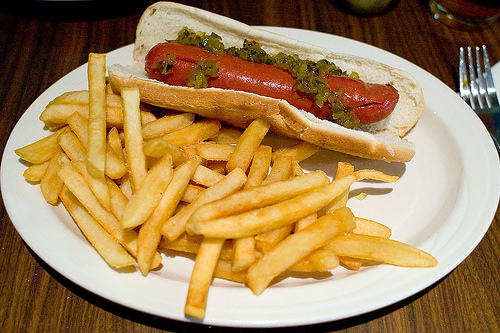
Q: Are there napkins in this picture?
A: No, there are no napkins.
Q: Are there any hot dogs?
A: Yes, there is a hot dog.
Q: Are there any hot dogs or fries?
A: Yes, there is a hot dog.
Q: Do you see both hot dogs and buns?
A: Yes, there are both a hot dog and a bun.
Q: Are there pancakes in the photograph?
A: No, there are no pancakes.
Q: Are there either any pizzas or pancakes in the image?
A: No, there are no pancakes or pizzas.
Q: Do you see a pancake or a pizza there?
A: No, there are no pancakes or pizzas.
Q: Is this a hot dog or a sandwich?
A: This is a hot dog.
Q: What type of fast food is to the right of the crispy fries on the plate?
A: The food is a hot dog.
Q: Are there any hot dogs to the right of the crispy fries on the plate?
A: Yes, there is a hot dog to the right of the fries.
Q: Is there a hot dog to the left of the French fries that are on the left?
A: No, the hot dog is to the right of the French fries.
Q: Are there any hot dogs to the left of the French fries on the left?
A: No, the hot dog is to the right of the French fries.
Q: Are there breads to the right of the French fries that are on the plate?
A: No, there is a hot dog to the right of the fries.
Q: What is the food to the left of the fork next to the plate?
A: The food is a hot dog.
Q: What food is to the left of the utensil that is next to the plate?
A: The food is a hot dog.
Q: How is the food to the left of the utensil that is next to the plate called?
A: The food is a hot dog.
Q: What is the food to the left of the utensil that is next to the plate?
A: The food is a hot dog.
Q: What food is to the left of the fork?
A: The food is a hot dog.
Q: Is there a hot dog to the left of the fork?
A: Yes, there is a hot dog to the left of the fork.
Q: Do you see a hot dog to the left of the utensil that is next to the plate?
A: Yes, there is a hot dog to the left of the fork.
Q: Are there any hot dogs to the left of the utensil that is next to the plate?
A: Yes, there is a hot dog to the left of the fork.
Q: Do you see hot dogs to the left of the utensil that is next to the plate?
A: Yes, there is a hot dog to the left of the fork.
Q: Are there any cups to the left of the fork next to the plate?
A: No, there is a hot dog to the left of the fork.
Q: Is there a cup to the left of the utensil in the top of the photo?
A: No, there is a hot dog to the left of the fork.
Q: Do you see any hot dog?
A: Yes, there is a hot dog.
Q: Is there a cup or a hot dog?
A: Yes, there is a hot dog.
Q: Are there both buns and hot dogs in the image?
A: Yes, there are both a hot dog and a bun.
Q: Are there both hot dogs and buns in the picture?
A: Yes, there are both a hot dog and a bun.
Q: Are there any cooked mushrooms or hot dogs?
A: Yes, there is a cooked hot dog.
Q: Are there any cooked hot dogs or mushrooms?
A: Yes, there is a cooked hot dog.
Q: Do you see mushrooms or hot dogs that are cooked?
A: Yes, the hot dog is cooked.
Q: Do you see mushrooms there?
A: No, there are no mushrooms.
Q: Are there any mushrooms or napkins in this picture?
A: No, there are no mushrooms or napkins.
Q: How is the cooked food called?
A: The food is a hot dog.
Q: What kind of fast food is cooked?
A: The fast food is a hot dog.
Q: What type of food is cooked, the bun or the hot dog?
A: The hot dog is cooked.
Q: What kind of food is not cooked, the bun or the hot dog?
A: The bun is not cooked.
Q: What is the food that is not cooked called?
A: The food is a bun.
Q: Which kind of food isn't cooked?
A: The food is a bun.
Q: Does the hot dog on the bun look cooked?
A: Yes, the hot dog is cooked.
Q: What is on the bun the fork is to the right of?
A: The hot dog is on the bun.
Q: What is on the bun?
A: The hot dog is on the bun.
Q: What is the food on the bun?
A: The food is a hot dog.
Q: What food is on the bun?
A: The food is a hot dog.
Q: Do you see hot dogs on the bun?
A: Yes, there is a hot dog on the bun.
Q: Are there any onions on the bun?
A: No, there is a hot dog on the bun.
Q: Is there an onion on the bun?
A: No, there is a hot dog on the bun.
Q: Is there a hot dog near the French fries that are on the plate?
A: Yes, there is a hot dog near the French fries.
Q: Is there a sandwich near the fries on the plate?
A: No, there is a hot dog near the French fries.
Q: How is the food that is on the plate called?
A: The food is a hot dog.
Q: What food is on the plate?
A: The food is a hot dog.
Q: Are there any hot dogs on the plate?
A: Yes, there is a hot dog on the plate.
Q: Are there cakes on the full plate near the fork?
A: No, there is a hot dog on the plate.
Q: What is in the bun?
A: The hot dog is in the bun.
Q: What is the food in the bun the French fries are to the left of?
A: The food is a hot dog.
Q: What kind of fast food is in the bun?
A: The food is a hot dog.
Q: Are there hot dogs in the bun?
A: Yes, there is a hot dog in the bun.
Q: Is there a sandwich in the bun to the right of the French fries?
A: No, there is a hot dog in the bun.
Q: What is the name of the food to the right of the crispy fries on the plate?
A: The food is a hot dog.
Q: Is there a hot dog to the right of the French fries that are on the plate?
A: Yes, there is a hot dog to the right of the French fries.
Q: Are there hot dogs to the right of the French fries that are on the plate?
A: Yes, there is a hot dog to the right of the French fries.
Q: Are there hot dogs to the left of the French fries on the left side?
A: No, the hot dog is to the right of the fries.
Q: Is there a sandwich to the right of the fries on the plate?
A: No, there is a hot dog to the right of the fries.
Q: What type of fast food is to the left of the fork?
A: The food is a hot dog.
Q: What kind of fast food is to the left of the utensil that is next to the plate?
A: The food is a hot dog.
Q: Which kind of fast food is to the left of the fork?
A: The food is a hot dog.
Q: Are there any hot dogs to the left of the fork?
A: Yes, there is a hot dog to the left of the fork.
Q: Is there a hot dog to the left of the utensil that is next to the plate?
A: Yes, there is a hot dog to the left of the fork.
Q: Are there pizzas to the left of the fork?
A: No, there is a hot dog to the left of the fork.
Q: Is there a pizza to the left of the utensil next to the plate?
A: No, there is a hot dog to the left of the fork.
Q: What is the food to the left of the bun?
A: The food is fries.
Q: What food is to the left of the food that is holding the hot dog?
A: The food is fries.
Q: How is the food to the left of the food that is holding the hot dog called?
A: The food is fries.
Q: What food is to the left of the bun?
A: The food is fries.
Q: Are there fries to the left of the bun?
A: Yes, there are fries to the left of the bun.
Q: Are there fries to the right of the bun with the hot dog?
A: No, the fries are to the left of the bun.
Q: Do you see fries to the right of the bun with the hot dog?
A: No, the fries are to the left of the bun.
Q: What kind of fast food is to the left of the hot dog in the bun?
A: The food is fries.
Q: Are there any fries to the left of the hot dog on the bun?
A: Yes, there are fries to the left of the hot dog.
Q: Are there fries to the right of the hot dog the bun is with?
A: No, the fries are to the left of the hot dog.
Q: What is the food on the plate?
A: The food is fries.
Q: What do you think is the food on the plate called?
A: The food is fries.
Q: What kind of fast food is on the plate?
A: The food is fries.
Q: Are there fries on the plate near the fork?
A: Yes, there are fries on the plate.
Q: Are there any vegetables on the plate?
A: No, there are fries on the plate.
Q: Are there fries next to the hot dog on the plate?
A: Yes, there are fries next to the hot dog.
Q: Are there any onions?
A: No, there are no onions.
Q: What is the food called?
A: The food is a bun.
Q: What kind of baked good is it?
A: The food is a bun.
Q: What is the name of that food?
A: This is a bun.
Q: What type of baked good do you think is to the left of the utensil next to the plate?
A: The food is a bun.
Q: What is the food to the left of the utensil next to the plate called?
A: The food is a bun.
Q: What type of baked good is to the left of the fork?
A: The food is a bun.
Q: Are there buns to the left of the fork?
A: Yes, there is a bun to the left of the fork.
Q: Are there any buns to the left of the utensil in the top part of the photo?
A: Yes, there is a bun to the left of the fork.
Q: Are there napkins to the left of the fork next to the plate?
A: No, there is a bun to the left of the fork.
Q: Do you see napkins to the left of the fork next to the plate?
A: No, there is a bun to the left of the fork.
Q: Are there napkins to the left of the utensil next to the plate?
A: No, there is a bun to the left of the fork.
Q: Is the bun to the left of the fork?
A: Yes, the bun is to the left of the fork.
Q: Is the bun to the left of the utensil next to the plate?
A: Yes, the bun is to the left of the fork.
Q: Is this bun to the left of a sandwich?
A: No, the bun is to the left of the fork.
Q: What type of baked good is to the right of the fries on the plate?
A: The food is a bun.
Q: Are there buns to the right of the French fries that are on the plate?
A: Yes, there is a bun to the right of the French fries.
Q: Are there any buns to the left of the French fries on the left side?
A: No, the bun is to the right of the French fries.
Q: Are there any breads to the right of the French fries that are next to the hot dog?
A: No, there is a bun to the right of the fries.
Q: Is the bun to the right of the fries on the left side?
A: Yes, the bun is to the right of the fries.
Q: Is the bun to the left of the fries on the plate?
A: No, the bun is to the right of the fries.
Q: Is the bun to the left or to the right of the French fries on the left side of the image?
A: The bun is to the right of the French fries.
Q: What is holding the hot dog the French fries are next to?
A: The bun is holding the hot dog.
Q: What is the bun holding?
A: The bun is holding the hot dog.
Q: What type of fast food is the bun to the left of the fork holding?
A: The bun is holding the hot dog.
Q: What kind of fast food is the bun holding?
A: The bun is holding the hot dog.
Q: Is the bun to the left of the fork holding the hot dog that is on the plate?
A: Yes, the bun is holding the hot dog.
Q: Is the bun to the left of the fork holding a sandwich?
A: No, the bun is holding the hot dog.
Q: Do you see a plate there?
A: Yes, there is a plate.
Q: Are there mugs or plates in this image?
A: Yes, there is a plate.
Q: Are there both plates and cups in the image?
A: No, there is a plate but no cups.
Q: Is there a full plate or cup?
A: Yes, there is a full plate.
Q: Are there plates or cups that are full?
A: Yes, the plate is full.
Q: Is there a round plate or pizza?
A: Yes, there is a round plate.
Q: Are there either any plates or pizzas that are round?
A: Yes, the plate is round.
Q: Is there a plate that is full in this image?
A: Yes, there is a full plate.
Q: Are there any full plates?
A: Yes, there is a full plate.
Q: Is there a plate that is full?
A: Yes, there is a plate that is full.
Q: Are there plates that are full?
A: Yes, there is a plate that is full.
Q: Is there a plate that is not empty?
A: Yes, there is an full plate.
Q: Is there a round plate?
A: Yes, there is a round plate.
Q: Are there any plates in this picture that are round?
A: Yes, there is a plate that is round.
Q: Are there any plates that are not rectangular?
A: Yes, there is a round plate.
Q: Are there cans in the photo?
A: No, there are no cans.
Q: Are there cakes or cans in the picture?
A: No, there are no cans or cakes.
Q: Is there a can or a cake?
A: No, there are no cans or cakes.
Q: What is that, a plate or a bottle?
A: That is a plate.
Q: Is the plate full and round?
A: Yes, the plate is full and round.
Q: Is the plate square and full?
A: No, the plate is full but round.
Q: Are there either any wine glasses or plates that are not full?
A: No, there is a plate but it is full.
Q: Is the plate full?
A: Yes, the plate is full.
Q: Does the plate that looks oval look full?
A: Yes, the plate is full.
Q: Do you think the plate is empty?
A: No, the plate is full.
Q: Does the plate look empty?
A: No, the plate is full.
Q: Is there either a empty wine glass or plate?
A: No, there is a plate but it is full.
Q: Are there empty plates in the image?
A: No, there is a plate but it is full.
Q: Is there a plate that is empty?
A: No, there is a plate but it is full.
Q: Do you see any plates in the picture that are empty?
A: No, there is a plate but it is full.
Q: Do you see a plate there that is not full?
A: No, there is a plate but it is full.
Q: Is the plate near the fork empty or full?
A: The plate is full.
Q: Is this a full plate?
A: Yes, this is a full plate.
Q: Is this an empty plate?
A: No, this is a full plate.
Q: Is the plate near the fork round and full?
A: Yes, the plate is round and full.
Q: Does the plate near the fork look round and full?
A: Yes, the plate is round and full.